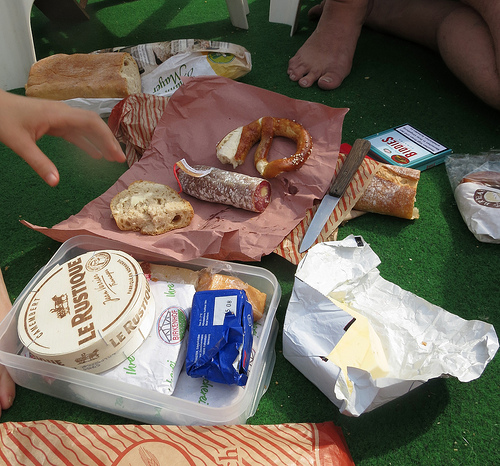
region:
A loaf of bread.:
[24, 51, 142, 99]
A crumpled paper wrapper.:
[278, 233, 498, 417]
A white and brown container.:
[16, 245, 156, 377]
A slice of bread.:
[107, 180, 194, 235]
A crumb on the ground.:
[358, 66, 372, 84]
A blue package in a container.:
[183, 286, 253, 386]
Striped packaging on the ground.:
[0, 420, 353, 465]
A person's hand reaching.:
[2, 91, 129, 188]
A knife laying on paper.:
[297, 137, 372, 254]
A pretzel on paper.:
[213, 112, 313, 182]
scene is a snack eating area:
[22, 8, 491, 452]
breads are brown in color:
[173, 125, 322, 193]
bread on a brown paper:
[134, 124, 375, 239]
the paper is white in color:
[324, 253, 432, 401]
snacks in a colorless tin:
[53, 239, 268, 404]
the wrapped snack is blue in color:
[198, 297, 253, 367]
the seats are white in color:
[238, 5, 313, 26]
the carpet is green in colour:
[402, 383, 499, 448]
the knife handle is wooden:
[330, 141, 373, 223]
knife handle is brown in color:
[326, 136, 383, 212]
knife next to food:
[290, 130, 378, 256]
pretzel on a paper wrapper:
[211, 108, 324, 182]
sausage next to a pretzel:
[169, 155, 277, 220]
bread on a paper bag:
[18, 45, 153, 106]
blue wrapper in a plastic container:
[176, 282, 261, 395]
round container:
[7, 242, 165, 377]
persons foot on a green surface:
[278, 0, 372, 100]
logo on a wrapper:
[151, 302, 195, 348]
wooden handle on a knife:
[323, 132, 377, 200]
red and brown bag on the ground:
[0, 409, 374, 464]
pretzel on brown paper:
[120, 78, 307, 269]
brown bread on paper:
[130, 175, 200, 237]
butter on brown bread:
[114, 163, 178, 245]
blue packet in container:
[157, 277, 259, 407]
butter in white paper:
[282, 238, 463, 433]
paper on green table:
[287, 235, 464, 433]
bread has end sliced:
[361, 154, 451, 268]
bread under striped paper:
[114, 100, 402, 242]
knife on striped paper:
[305, 144, 366, 289]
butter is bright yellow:
[314, 298, 389, 386]